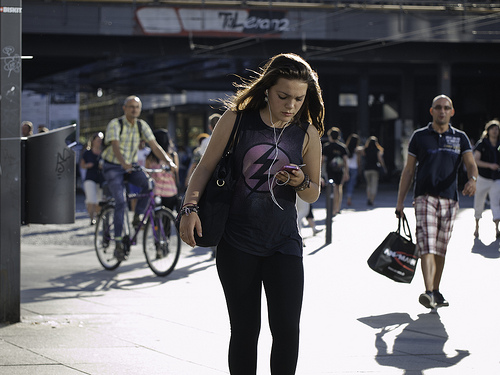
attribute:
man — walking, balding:
[368, 89, 480, 312]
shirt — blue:
[405, 118, 475, 204]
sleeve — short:
[458, 134, 473, 163]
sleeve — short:
[403, 131, 425, 160]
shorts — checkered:
[407, 190, 463, 261]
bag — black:
[367, 209, 420, 287]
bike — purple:
[88, 151, 186, 278]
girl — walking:
[174, 49, 326, 372]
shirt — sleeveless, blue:
[221, 109, 312, 261]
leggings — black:
[213, 236, 304, 374]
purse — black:
[175, 92, 247, 255]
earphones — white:
[262, 90, 303, 214]